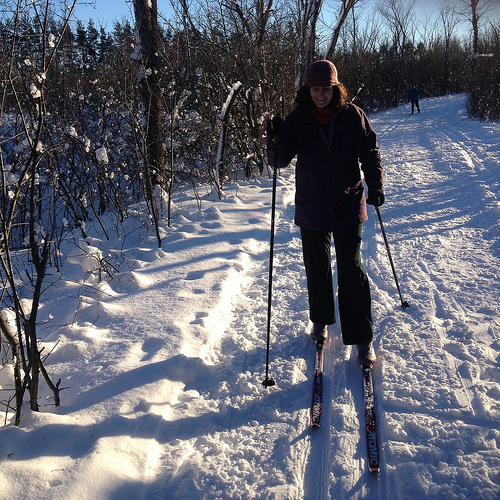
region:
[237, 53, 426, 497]
Woman is trying to ski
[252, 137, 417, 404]
Two black skiing poles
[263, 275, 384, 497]
Two red and white skis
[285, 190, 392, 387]
Woman wearing black snow pants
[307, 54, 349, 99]
Woman has red hat on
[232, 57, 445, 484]
Woman with dark brown curly hair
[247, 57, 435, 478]
Woman having a lot of fun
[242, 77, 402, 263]
Woman wearing dark brown snow jacket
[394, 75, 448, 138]
Another skier in the distance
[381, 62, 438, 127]
Skier is trying to catch up to woman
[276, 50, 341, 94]
The lady is wearing a brown hat.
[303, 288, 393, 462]
the lady is wearing skis.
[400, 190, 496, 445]
Tracks in the snow.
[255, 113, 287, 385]
The woman is holding a ski pole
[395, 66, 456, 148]
A person skiing on the trail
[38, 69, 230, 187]
Snow on the trees.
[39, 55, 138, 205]
The trees do not have any leaves.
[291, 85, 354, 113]
The lady is smiling.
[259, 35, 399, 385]
The lady is skiing in the snow.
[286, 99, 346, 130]
The lady is wearing a scarf around her neck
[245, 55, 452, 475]
this woman is on skis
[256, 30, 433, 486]
this woman is skiing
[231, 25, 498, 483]
she is leisurely skiing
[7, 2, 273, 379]
there are no leaves on these bushes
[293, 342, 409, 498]
her skis are very thin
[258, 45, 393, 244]
she is wearing a purple jacket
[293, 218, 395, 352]
she is wearing black pants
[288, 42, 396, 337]
she is wearing a hat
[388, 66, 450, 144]
there is another person skiing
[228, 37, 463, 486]
she is going down a hill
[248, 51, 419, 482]
A woman is skiing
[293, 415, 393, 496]
Ski tracks on the snow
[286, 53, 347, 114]
Hat on woman's head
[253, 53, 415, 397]
Woman is holding two ski poles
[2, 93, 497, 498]
Shadows are on the snow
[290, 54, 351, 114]
Woman has brown hair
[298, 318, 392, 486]
A pair of skis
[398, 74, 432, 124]
A person in the background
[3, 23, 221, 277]
Snow on tree branches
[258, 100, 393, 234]
A dark purple jacket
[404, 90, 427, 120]
cross country skier on a trail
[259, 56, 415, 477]
cross country skier on a trail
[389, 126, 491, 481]
tracks along a cross country ski trail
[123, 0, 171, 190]
tree trunk on the side of a cross country trail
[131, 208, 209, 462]
footprints in white snow by a trail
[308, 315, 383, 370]
white cross country ski boots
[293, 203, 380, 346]
black pants on a cross country skier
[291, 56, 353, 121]
knit hat on a woman with long brown hair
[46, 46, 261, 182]
brush on the side of a cross country ski trail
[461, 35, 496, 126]
brush on the side of a cross country ski